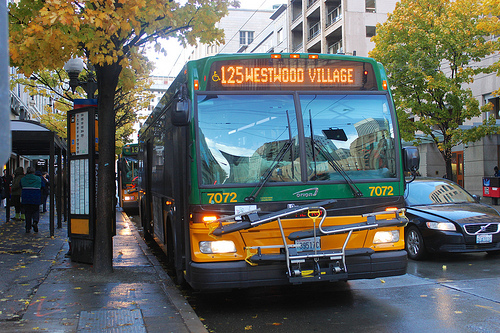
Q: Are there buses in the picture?
A: Yes, there is a bus.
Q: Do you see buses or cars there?
A: Yes, there is a bus.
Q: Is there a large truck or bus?
A: Yes, there is a large bus.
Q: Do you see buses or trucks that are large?
A: Yes, the bus is large.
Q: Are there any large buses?
A: Yes, there is a large bus.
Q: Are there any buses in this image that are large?
A: Yes, there is a bus that is large.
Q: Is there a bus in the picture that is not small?
A: Yes, there is a large bus.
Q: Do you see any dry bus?
A: Yes, there is a dry bus.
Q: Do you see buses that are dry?
A: Yes, there is a bus that is dry.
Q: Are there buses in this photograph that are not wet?
A: Yes, there is a dry bus.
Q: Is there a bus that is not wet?
A: Yes, there is a dry bus.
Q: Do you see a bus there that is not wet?
A: Yes, there is a dry bus.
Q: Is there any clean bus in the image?
A: Yes, there is a clean bus.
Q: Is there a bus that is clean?
A: Yes, there is a bus that is clean.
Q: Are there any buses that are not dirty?
A: Yes, there is a clean bus.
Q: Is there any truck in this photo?
A: No, there are no trucks.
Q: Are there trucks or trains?
A: No, there are no trucks or trains.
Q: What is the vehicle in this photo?
A: The vehicle is a bus.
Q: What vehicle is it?
A: The vehicle is a bus.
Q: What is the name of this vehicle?
A: This is a bus.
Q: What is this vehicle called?
A: This is a bus.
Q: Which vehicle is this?
A: This is a bus.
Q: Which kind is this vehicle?
A: This is a bus.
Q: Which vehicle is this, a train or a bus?
A: This is a bus.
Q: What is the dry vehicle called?
A: The vehicle is a bus.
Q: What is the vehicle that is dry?
A: The vehicle is a bus.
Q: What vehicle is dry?
A: The vehicle is a bus.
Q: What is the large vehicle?
A: The vehicle is a bus.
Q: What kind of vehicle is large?
A: The vehicle is a bus.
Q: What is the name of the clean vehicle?
A: The vehicle is a bus.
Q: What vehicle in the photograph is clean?
A: The vehicle is a bus.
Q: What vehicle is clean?
A: The vehicle is a bus.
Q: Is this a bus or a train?
A: This is a bus.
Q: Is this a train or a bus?
A: This is a bus.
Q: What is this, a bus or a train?
A: This is a bus.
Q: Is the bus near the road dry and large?
A: Yes, the bus is dry and large.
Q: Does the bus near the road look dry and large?
A: Yes, the bus is dry and large.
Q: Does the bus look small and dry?
A: No, the bus is dry but large.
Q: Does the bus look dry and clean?
A: Yes, the bus is dry and clean.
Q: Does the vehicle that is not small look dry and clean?
A: Yes, the bus is dry and clean.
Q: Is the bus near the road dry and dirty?
A: No, the bus is dry but clean.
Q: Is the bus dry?
A: Yes, the bus is dry.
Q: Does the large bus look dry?
A: Yes, the bus is dry.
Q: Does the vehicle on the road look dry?
A: Yes, the bus is dry.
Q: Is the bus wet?
A: No, the bus is dry.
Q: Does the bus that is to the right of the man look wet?
A: No, the bus is dry.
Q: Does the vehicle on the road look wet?
A: No, the bus is dry.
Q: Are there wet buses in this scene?
A: No, there is a bus but it is dry.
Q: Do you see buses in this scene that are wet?
A: No, there is a bus but it is dry.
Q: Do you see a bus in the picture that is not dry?
A: No, there is a bus but it is dry.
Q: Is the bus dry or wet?
A: The bus is dry.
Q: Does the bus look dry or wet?
A: The bus is dry.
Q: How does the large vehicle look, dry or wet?
A: The bus is dry.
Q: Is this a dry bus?
A: Yes, this is a dry bus.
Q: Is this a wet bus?
A: No, this is a dry bus.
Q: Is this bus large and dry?
A: Yes, the bus is large and dry.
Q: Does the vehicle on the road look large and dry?
A: Yes, the bus is large and dry.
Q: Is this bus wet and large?
A: No, the bus is large but dry.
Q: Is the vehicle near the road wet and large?
A: No, the bus is large but dry.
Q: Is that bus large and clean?
A: Yes, the bus is large and clean.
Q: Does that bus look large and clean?
A: Yes, the bus is large and clean.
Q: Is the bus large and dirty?
A: No, the bus is large but clean.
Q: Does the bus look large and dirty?
A: No, the bus is large but clean.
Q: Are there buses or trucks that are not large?
A: No, there is a bus but it is large.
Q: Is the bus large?
A: Yes, the bus is large.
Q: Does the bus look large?
A: Yes, the bus is large.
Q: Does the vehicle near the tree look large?
A: Yes, the bus is large.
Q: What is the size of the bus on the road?
A: The bus is large.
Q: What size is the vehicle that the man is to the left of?
A: The bus is large.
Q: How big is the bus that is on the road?
A: The bus is large.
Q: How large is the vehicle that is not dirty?
A: The bus is large.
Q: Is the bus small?
A: No, the bus is large.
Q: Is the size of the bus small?
A: No, the bus is large.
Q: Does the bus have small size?
A: No, the bus is large.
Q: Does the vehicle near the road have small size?
A: No, the bus is large.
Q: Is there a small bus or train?
A: No, there is a bus but it is large.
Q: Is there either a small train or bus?
A: No, there is a bus but it is large.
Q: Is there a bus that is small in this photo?
A: No, there is a bus but it is large.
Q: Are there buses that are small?
A: No, there is a bus but it is large.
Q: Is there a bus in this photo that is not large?
A: No, there is a bus but it is large.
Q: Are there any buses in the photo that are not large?
A: No, there is a bus but it is large.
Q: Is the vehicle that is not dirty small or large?
A: The bus is large.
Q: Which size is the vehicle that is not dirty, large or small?
A: The bus is large.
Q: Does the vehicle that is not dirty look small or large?
A: The bus is large.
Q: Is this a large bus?
A: Yes, this is a large bus.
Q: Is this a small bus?
A: No, this is a large bus.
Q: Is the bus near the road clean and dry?
A: Yes, the bus is clean and dry.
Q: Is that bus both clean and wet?
A: No, the bus is clean but dry.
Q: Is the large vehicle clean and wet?
A: No, the bus is clean but dry.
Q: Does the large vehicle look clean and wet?
A: No, the bus is clean but dry.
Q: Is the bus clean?
A: Yes, the bus is clean.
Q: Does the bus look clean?
A: Yes, the bus is clean.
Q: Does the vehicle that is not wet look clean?
A: Yes, the bus is clean.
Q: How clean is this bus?
A: The bus is clean.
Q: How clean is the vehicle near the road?
A: The bus is clean.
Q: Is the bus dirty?
A: No, the bus is clean.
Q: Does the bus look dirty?
A: No, the bus is clean.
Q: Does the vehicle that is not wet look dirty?
A: No, the bus is clean.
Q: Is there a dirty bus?
A: No, there is a bus but it is clean.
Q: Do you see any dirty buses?
A: No, there is a bus but it is clean.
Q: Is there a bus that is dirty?
A: No, there is a bus but it is clean.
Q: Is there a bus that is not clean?
A: No, there is a bus but it is clean.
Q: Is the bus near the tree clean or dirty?
A: The bus is clean.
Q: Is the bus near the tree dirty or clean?
A: The bus is clean.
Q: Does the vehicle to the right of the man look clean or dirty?
A: The bus is clean.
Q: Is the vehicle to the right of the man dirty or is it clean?
A: The bus is clean.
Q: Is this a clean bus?
A: Yes, this is a clean bus.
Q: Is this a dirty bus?
A: No, this is a clean bus.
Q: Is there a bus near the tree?
A: Yes, there is a bus near the tree.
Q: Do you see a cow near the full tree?
A: No, there is a bus near the tree.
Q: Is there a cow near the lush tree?
A: No, there is a bus near the tree.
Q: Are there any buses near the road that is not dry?
A: Yes, there is a bus near the road.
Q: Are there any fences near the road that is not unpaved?
A: No, there is a bus near the road.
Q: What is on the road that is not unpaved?
A: The bus is on the road.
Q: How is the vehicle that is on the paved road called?
A: The vehicle is a bus.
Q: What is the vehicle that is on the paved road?
A: The vehicle is a bus.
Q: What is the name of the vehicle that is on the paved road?
A: The vehicle is a bus.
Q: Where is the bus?
A: The bus is on the road.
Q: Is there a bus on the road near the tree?
A: Yes, there is a bus on the road.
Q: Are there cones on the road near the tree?
A: No, there is a bus on the road.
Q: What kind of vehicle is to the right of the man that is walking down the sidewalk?
A: The vehicle is a bus.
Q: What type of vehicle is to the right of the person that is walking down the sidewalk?
A: The vehicle is a bus.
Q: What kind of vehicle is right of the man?
A: The vehicle is a bus.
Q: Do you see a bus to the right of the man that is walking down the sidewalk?
A: Yes, there is a bus to the right of the man.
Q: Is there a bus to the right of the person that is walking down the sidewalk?
A: Yes, there is a bus to the right of the man.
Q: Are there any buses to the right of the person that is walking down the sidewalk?
A: Yes, there is a bus to the right of the man.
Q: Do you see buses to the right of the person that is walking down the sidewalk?
A: Yes, there is a bus to the right of the man.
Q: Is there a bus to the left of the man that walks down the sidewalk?
A: No, the bus is to the right of the man.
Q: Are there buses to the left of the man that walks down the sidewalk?
A: No, the bus is to the right of the man.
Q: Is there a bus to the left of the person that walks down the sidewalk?
A: No, the bus is to the right of the man.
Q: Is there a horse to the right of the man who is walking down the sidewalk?
A: No, there is a bus to the right of the man.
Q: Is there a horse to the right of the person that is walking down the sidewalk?
A: No, there is a bus to the right of the man.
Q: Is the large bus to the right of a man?
A: Yes, the bus is to the right of a man.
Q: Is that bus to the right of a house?
A: No, the bus is to the right of a man.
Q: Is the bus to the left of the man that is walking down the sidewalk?
A: No, the bus is to the right of the man.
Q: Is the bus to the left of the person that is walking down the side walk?
A: No, the bus is to the right of the man.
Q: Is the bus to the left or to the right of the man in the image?
A: The bus is to the right of the man.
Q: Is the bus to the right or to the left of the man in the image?
A: The bus is to the right of the man.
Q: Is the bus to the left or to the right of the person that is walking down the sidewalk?
A: The bus is to the right of the man.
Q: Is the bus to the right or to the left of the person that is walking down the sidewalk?
A: The bus is to the right of the man.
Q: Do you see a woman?
A: No, there are no women.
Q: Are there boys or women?
A: No, there are no women or boys.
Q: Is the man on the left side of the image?
A: Yes, the man is on the left of the image.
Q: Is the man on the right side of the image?
A: No, the man is on the left of the image.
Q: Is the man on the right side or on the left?
A: The man is on the left of the image.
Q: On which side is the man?
A: The man is on the left of the image.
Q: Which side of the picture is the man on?
A: The man is on the left of the image.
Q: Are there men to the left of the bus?
A: Yes, there is a man to the left of the bus.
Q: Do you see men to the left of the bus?
A: Yes, there is a man to the left of the bus.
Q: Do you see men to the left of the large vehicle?
A: Yes, there is a man to the left of the bus.